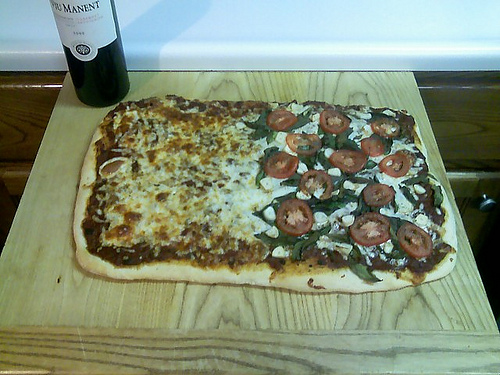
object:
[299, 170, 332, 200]
tomato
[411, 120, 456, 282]
crust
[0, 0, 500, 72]
counter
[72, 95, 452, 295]
pizza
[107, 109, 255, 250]
yellow cheese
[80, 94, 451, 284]
brown crust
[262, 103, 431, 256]
nuts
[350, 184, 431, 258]
tomatoes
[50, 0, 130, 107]
bottle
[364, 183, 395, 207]
tomato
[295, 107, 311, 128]
basil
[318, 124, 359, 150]
basil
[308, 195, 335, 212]
basil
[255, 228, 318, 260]
basil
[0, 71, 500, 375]
board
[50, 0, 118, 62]
label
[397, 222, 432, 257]
tomato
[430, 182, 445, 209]
greens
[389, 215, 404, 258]
greens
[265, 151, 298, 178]
tomato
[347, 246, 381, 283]
greens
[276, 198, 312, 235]
tomato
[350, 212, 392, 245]
tomato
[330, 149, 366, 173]
tomato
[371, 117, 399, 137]
tomato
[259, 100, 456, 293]
half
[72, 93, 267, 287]
half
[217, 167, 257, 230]
cheese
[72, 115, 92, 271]
crust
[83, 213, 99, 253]
sauce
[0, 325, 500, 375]
seam